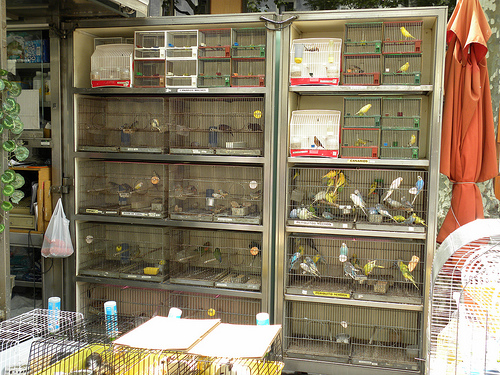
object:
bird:
[399, 24, 417, 40]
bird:
[395, 61, 411, 73]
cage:
[165, 28, 196, 61]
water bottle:
[44, 295, 62, 332]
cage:
[1, 305, 85, 373]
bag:
[39, 192, 76, 258]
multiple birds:
[319, 168, 348, 194]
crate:
[285, 166, 426, 230]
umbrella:
[438, 1, 499, 238]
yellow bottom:
[47, 341, 161, 374]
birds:
[211, 246, 225, 263]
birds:
[216, 121, 234, 137]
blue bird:
[413, 175, 425, 205]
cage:
[77, 162, 168, 217]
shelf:
[72, 213, 268, 231]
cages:
[80, 95, 167, 153]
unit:
[60, 13, 272, 343]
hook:
[48, 178, 73, 194]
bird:
[394, 258, 417, 289]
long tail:
[406, 274, 418, 291]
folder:
[111, 315, 221, 350]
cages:
[190, 321, 284, 373]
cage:
[292, 37, 341, 85]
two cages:
[75, 159, 264, 227]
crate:
[287, 233, 424, 307]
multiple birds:
[339, 242, 378, 280]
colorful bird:
[289, 249, 303, 268]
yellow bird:
[335, 171, 347, 191]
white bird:
[382, 175, 404, 200]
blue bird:
[338, 242, 350, 260]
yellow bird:
[322, 170, 337, 180]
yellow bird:
[323, 192, 340, 205]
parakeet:
[354, 102, 373, 115]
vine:
[2, 72, 24, 231]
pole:
[1, 1, 11, 320]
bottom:
[71, 276, 432, 367]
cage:
[166, 57, 200, 90]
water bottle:
[103, 299, 119, 337]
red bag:
[42, 237, 73, 255]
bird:
[115, 243, 121, 256]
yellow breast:
[116, 248, 121, 251]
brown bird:
[312, 136, 324, 152]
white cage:
[289, 108, 340, 156]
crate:
[382, 22, 423, 57]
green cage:
[344, 22, 381, 55]